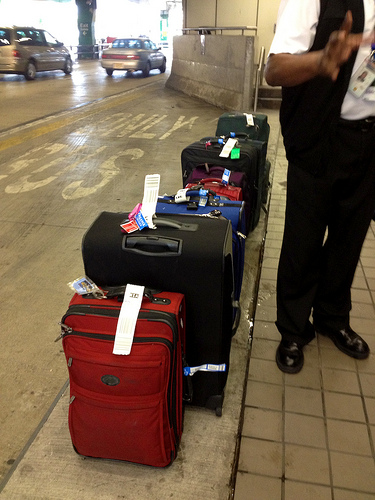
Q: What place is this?
A: It is a sidewalk.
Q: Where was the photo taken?
A: It was taken at the sidewalk.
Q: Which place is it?
A: It is a sidewalk.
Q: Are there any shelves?
A: No, there are no shelves.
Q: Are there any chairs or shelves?
A: No, there are no shelves or chairs.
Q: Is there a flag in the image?
A: No, there are no flags.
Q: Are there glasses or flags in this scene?
A: No, there are no flags or glasses.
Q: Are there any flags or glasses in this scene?
A: No, there are no flags or glasses.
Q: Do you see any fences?
A: No, there are no fences.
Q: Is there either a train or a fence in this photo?
A: No, there are no fences or trains.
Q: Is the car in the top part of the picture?
A: Yes, the car is in the top of the image.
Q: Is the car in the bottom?
A: No, the car is in the top of the image.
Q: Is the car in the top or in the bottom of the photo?
A: The car is in the top of the image.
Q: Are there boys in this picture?
A: No, there are no boys.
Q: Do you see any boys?
A: No, there are no boys.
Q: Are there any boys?
A: No, there are no boys.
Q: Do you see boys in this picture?
A: No, there are no boys.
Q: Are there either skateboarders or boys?
A: No, there are no boys or skateboarders.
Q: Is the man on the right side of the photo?
A: Yes, the man is on the right of the image.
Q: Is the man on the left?
A: No, the man is on the right of the image.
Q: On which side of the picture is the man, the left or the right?
A: The man is on the right of the image.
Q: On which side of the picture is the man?
A: The man is on the right of the image.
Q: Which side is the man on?
A: The man is on the right of the image.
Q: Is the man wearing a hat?
A: No, the man is wearing a shoe.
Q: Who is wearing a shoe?
A: The man is wearing a shoe.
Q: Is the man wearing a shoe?
A: Yes, the man is wearing a shoe.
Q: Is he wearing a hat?
A: No, the man is wearing a shoe.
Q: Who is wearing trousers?
A: The man is wearing trousers.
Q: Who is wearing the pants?
A: The man is wearing trousers.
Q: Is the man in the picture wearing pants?
A: Yes, the man is wearing pants.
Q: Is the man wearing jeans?
A: No, the man is wearing pants.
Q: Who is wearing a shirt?
A: The man is wearing a shirt.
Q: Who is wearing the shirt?
A: The man is wearing a shirt.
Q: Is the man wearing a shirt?
A: Yes, the man is wearing a shirt.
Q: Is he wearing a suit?
A: No, the man is wearing a shirt.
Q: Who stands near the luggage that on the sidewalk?
A: The man stands near the luggage.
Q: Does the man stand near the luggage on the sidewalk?
A: Yes, the man stands near the luggage.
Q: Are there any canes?
A: No, there are no canes.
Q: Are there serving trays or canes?
A: No, there are no canes or serving trays.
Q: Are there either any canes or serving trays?
A: No, there are no canes or serving trays.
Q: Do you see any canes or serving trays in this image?
A: No, there are no canes or serving trays.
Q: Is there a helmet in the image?
A: No, there are no helmets.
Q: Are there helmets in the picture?
A: No, there are no helmets.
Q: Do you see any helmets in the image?
A: No, there are no helmets.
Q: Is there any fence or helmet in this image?
A: No, there are no helmets or fences.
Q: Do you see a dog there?
A: No, there are no dogs.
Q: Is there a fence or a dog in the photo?
A: No, there are no dogs or fences.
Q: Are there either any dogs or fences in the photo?
A: No, there are no dogs or fences.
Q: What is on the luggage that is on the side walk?
A: The tag is on the luggage.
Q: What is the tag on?
A: The tag is on the luggage.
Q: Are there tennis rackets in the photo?
A: No, there are no tennis rackets.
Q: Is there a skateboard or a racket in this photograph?
A: No, there are no rackets or skateboards.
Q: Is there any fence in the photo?
A: No, there are no fences.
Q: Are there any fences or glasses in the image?
A: No, there are no fences or glasses.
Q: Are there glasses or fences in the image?
A: No, there are no fences or glasses.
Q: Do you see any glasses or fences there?
A: No, there are no fences or glasses.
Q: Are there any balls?
A: No, there are no balls.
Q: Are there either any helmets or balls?
A: No, there are no balls or helmets.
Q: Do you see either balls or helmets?
A: No, there are no balls or helmets.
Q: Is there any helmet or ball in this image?
A: No, there are no balls or helmets.